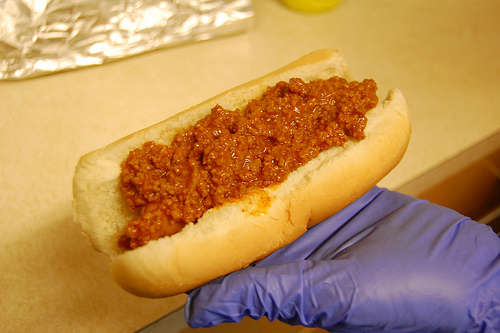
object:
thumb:
[184, 261, 354, 328]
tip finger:
[183, 292, 228, 332]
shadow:
[0, 216, 190, 331]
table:
[2, 2, 497, 331]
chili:
[116, 70, 379, 251]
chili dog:
[119, 62, 372, 209]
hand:
[180, 184, 498, 330]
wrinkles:
[183, 185, 496, 332]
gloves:
[181, 178, 497, 331]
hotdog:
[54, 47, 417, 302]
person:
[194, 188, 479, 320]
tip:
[184, 284, 234, 330]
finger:
[184, 267, 359, 319]